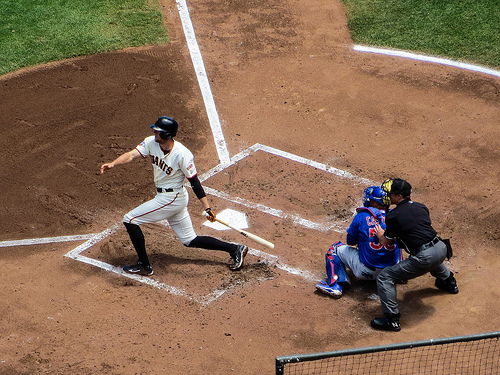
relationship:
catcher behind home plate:
[322, 181, 397, 294] [207, 209, 251, 232]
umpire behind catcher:
[378, 180, 463, 322] [322, 181, 397, 294]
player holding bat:
[96, 117, 249, 275] [205, 209, 283, 253]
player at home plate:
[96, 117, 249, 275] [207, 209, 251, 232]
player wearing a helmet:
[96, 117, 249, 275] [149, 117, 181, 139]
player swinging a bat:
[96, 117, 249, 275] [205, 209, 283, 253]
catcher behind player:
[322, 181, 397, 294] [96, 117, 249, 275]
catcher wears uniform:
[322, 181, 397, 294] [327, 211, 398, 274]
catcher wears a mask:
[322, 181, 397, 294] [358, 186, 371, 207]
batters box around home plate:
[195, 145, 380, 238] [207, 209, 251, 232]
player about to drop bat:
[96, 117, 249, 275] [205, 209, 283, 253]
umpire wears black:
[378, 180, 463, 322] [399, 206, 426, 234]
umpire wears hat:
[378, 180, 463, 322] [383, 178, 412, 197]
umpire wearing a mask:
[378, 180, 463, 322] [379, 180, 391, 210]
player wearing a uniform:
[96, 117, 249, 275] [132, 138, 199, 240]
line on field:
[171, 3, 234, 152] [4, 2, 498, 327]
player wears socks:
[96, 117, 249, 275] [126, 222, 159, 270]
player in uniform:
[96, 117, 249, 275] [132, 138, 199, 240]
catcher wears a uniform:
[322, 181, 397, 294] [327, 211, 398, 274]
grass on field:
[1, 2, 165, 56] [4, 2, 498, 327]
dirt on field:
[227, 21, 383, 135] [4, 2, 498, 327]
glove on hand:
[203, 203, 216, 225] [100, 159, 113, 172]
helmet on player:
[149, 117, 181, 139] [96, 117, 249, 275]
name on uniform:
[150, 153, 181, 177] [132, 138, 199, 240]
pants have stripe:
[132, 190, 192, 238] [134, 194, 181, 228]